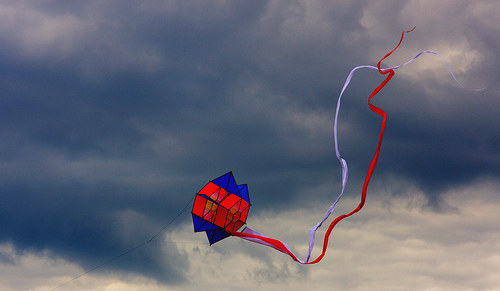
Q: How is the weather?
A: It is stormy.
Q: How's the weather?
A: It is stormy.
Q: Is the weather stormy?
A: Yes, it is stormy.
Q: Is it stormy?
A: Yes, it is stormy.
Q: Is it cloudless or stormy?
A: It is stormy.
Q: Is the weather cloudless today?
A: No, it is stormy.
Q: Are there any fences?
A: No, there are no fences.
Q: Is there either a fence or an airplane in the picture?
A: No, there are no fences or airplanes.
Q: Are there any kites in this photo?
A: Yes, there is a kite.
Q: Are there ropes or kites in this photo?
A: Yes, there is a kite.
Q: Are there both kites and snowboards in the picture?
A: No, there is a kite but no snowboards.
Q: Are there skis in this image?
A: No, there are no skis.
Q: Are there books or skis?
A: No, there are no skis or books.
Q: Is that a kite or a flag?
A: That is a kite.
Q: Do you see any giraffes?
A: No, there are no giraffes.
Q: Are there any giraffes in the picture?
A: No, there are no giraffes.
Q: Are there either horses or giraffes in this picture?
A: No, there are no giraffes or horses.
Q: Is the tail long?
A: Yes, the tail is long.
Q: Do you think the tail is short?
A: No, the tail is long.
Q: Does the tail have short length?
A: No, the tail is long.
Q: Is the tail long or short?
A: The tail is long.